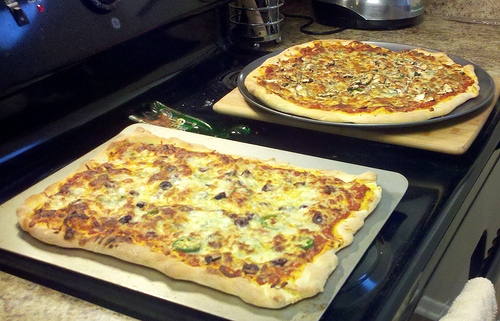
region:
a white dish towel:
[450, 276, 496, 316]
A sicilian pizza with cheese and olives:
[21, 138, 378, 309]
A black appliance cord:
[307, 15, 352, 36]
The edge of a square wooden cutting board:
[401, 116, 493, 154]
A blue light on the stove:
[2, 5, 44, 45]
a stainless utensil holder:
[229, 6, 283, 49]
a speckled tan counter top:
[4, 286, 101, 319]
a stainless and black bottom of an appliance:
[342, 4, 431, 25]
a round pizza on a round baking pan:
[242, 41, 475, 118]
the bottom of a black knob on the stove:
[77, 1, 124, 18]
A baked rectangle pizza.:
[13, 122, 384, 307]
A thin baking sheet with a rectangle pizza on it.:
[0, 120, 406, 320]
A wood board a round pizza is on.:
[211, 65, 498, 155]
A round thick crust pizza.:
[246, 36, 479, 124]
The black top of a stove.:
[0, 0, 496, 315]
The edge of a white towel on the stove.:
[438, 278, 499, 320]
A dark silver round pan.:
[236, 40, 494, 128]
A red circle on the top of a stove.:
[36, 2, 44, 13]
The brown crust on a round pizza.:
[243, 38, 478, 125]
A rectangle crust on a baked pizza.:
[15, 124, 378, 309]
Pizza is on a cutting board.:
[236, 45, 488, 161]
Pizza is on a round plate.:
[243, 58, 467, 138]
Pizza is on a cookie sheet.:
[41, 130, 387, 300]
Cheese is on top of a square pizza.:
[90, 148, 353, 316]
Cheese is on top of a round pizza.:
[267, 42, 457, 129]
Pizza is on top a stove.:
[10, 15, 497, 320]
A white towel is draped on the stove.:
[438, 255, 492, 319]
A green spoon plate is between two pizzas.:
[133, 97, 253, 147]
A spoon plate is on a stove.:
[127, 101, 245, 146]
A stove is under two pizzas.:
[10, 10, 496, 307]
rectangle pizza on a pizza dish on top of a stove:
[18, 126, 418, 318]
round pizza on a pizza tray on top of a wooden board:
[235, 26, 492, 144]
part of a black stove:
[392, 214, 497, 313]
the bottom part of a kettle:
[317, 0, 428, 32]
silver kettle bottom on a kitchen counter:
[312, 0, 439, 32]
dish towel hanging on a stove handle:
[425, 273, 495, 320]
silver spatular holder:
[225, 6, 288, 55]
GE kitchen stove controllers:
[2, 6, 214, 82]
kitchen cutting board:
[204, 91, 240, 119]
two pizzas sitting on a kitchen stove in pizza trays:
[5, 11, 492, 317]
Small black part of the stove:
[421, 165, 447, 190]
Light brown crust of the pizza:
[248, 288, 268, 303]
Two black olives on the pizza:
[121, 213, 133, 224]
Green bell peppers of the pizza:
[171, 235, 200, 256]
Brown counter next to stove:
[435, 25, 466, 47]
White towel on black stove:
[438, 273, 497, 319]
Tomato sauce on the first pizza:
[356, 183, 368, 194]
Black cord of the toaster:
[299, 14, 314, 34]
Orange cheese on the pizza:
[294, 274, 298, 281]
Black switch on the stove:
[11, 8, 34, 28]